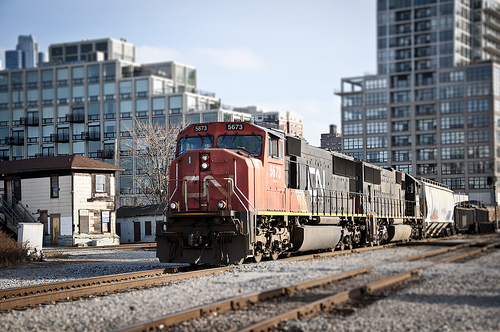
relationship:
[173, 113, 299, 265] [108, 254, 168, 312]
train on tracks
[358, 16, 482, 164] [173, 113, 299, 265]
building near train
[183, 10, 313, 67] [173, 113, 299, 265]
sky above train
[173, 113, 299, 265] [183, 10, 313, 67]
train below sky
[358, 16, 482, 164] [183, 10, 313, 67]
building in sky